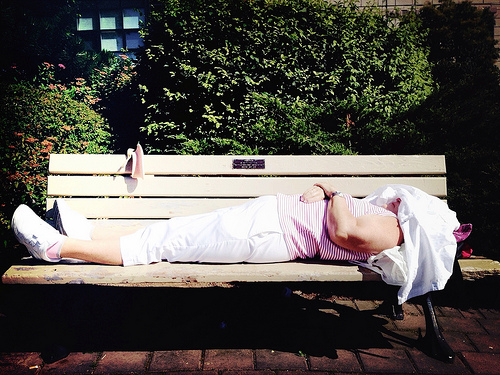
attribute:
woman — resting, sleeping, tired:
[19, 189, 477, 298]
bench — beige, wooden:
[57, 150, 460, 285]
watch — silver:
[325, 188, 342, 200]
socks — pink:
[44, 239, 75, 260]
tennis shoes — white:
[13, 198, 87, 269]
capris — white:
[124, 217, 290, 265]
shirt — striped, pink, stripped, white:
[278, 202, 388, 256]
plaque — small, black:
[224, 155, 271, 173]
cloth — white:
[396, 185, 456, 268]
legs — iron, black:
[402, 301, 455, 374]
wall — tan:
[340, 9, 498, 74]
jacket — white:
[387, 193, 465, 286]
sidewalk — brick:
[49, 318, 421, 375]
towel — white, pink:
[409, 210, 472, 283]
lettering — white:
[239, 161, 258, 167]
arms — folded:
[318, 182, 371, 254]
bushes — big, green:
[15, 70, 430, 153]